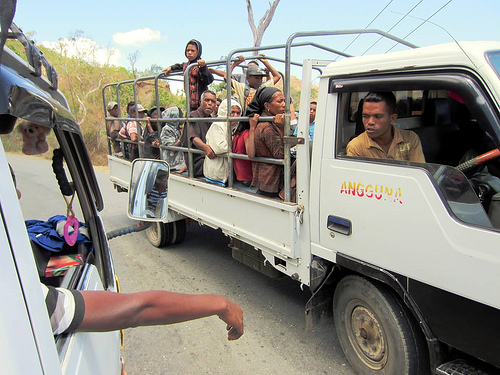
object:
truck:
[305, 33, 498, 340]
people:
[140, 105, 166, 159]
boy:
[223, 53, 281, 116]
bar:
[153, 70, 168, 159]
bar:
[183, 62, 197, 177]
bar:
[151, 118, 189, 123]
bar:
[227, 116, 276, 121]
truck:
[98, 19, 497, 373]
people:
[158, 106, 188, 173]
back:
[0, 25, 318, 298]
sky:
[18, 2, 498, 70]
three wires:
[318, 1, 458, 66]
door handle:
[327, 214, 353, 236]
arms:
[257, 53, 281, 85]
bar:
[224, 55, 233, 187]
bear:
[13, 119, 52, 156]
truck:
[4, 87, 182, 334]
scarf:
[231, 84, 279, 136]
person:
[119, 101, 138, 162]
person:
[181, 90, 218, 178]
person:
[245, 85, 296, 201]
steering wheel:
[453, 147, 499, 172]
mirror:
[125, 158, 171, 223]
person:
[202, 98, 241, 184]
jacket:
[170, 39, 214, 112]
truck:
[110, 51, 496, 374]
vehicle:
[101, 27, 500, 375]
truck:
[98, 89, 469, 307]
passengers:
[157, 106, 189, 175]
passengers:
[106, 101, 127, 158]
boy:
[293, 101, 318, 140]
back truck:
[101, 27, 499, 375]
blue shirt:
[293, 122, 315, 138]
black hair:
[310, 101, 317, 105]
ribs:
[101, 28, 419, 224]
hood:
[217, 98, 242, 125]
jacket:
[202, 98, 242, 184]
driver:
[345, 90, 425, 163]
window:
[328, 63, 500, 232]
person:
[40, 281, 243, 340]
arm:
[42, 280, 245, 339]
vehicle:
[0, 0, 171, 375]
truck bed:
[106, 130, 310, 292]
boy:
[161, 39, 215, 112]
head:
[259, 86, 287, 116]